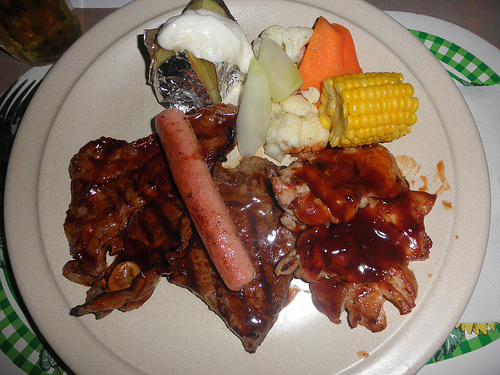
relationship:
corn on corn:
[312, 58, 420, 154] [316, 70, 420, 147]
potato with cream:
[246, 66, 324, 156] [161, 8, 247, 60]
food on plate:
[59, 10, 421, 347] [136, 326, 209, 372]